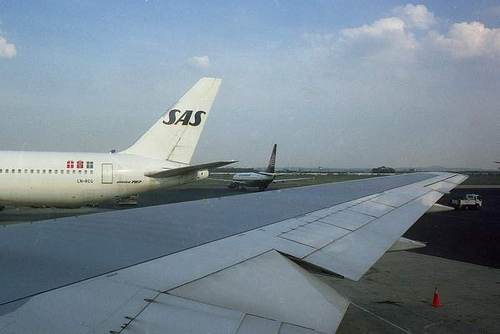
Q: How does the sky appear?
A: Cloudy.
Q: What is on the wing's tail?
A: SAS.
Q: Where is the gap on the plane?
A: Wing.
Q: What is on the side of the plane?
A: Windows.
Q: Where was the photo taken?
A: Airport runway.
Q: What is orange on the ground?
A: Safety cone.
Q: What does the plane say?
A: SAS.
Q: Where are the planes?
A: The runway.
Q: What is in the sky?
A: Clouds.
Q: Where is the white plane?
A: Left side.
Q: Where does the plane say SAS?
A: Vertical stabilizer.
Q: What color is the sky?
A: Blue.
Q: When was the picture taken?
A: Daytime.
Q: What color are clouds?
A: White.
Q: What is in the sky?
A: Clouds.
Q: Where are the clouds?
A: In the sky.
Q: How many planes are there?
A: Three.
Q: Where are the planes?
A: On the ground.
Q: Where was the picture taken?
A: At an airport.